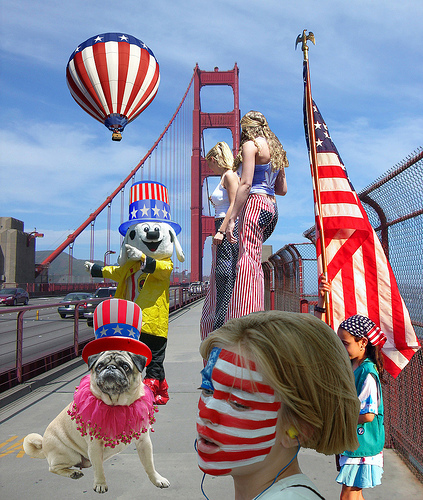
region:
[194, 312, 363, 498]
Girl with American flag painted on her face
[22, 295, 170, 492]
Dog with a pink tutu around its neck and an American flag hat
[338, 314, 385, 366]
Flag bandana on girl's head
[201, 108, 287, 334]
Two blonde women on stilts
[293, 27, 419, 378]
American flag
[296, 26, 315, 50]
Eagle on top of American flag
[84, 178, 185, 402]
Person dressed in a dog costume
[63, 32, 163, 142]
Hot air balloon in the sky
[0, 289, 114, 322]
Cars on the bridge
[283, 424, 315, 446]
Ear bud in girl's ear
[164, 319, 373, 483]
the head of a woman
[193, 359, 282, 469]
the facepainting of a woman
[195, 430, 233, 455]
the mouth of a woman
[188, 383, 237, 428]
the nose of a woman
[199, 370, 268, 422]
the eyes of a woman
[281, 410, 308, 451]
the ear of a woman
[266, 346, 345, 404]
the hair of a woman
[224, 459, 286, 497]
the neck of a woman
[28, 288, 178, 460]
a pug wearing a hat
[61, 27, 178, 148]
a large flag air balloon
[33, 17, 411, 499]
so much american pride in one picture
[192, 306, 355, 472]
a girl with american flag face paint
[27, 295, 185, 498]
a pug in an american flag hat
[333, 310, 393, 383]
a girl in a flag banana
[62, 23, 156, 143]
an american flag hot airballoon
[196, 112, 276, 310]
women in american flag pants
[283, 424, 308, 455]
yellow and blue ear plugs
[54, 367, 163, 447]
pink ruffle dog collar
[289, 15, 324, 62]
eagle on a flag pole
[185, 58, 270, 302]
golden gate bridge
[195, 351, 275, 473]
face paint of american flag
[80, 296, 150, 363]
american flag themed hat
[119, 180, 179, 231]
american flag themed hat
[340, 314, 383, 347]
american flag themed bandana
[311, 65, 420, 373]
american flag on pole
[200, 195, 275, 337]
woman wearing american flag themed pants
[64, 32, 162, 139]
american flag themed ballon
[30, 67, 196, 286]
red pole of bridge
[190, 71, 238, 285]
red metal structure of bridge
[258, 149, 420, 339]
red chain fence of bridge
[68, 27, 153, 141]
balloon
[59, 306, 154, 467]
dog with hat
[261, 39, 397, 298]
flag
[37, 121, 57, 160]
white clouds in blue sky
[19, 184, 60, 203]
white clouds in blue sky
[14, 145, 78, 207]
white clouds in blue sky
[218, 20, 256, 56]
white clouds in blue sky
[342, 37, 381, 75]
white clouds in blue sky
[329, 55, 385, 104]
white clouds in blue sky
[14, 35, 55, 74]
white clouds in blue sky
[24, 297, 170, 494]
pug is wearing an Uncle Sam hat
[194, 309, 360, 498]
woman has an American flag painted on her face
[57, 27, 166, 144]
A red white and blue hot air baloon.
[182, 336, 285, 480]
A young girls face painted in red white and blue.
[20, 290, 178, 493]
A dog wearing a red white and blue top hat.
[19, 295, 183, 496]
A dog wearing a pink tutu around its neck.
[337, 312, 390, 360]
A young girl wearing a red white and blue bandanna on her head.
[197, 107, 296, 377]
Two blonde ladies on stilts.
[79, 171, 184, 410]
A white dog costume wearing a red white and blue hat.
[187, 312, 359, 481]
A young girl with yellow ear plugs in her ears.